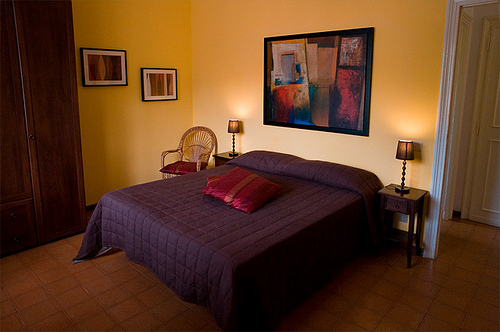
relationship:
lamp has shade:
[225, 117, 242, 156] [225, 118, 241, 133]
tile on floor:
[326, 279, 391, 329] [0, 207, 500, 329]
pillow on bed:
[202, 166, 283, 214] [136, 195, 262, 280]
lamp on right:
[394, 138, 414, 193] [377, 182, 428, 268]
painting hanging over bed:
[83, 49, 127, 85] [70, 149, 383, 331]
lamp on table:
[391, 131, 419, 201] [376, 181, 429, 275]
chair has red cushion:
[158, 122, 218, 179] [158, 150, 206, 173]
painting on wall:
[80, 46, 127, 86] [73, 0, 190, 203]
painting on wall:
[138, 66, 178, 99] [73, 0, 190, 203]